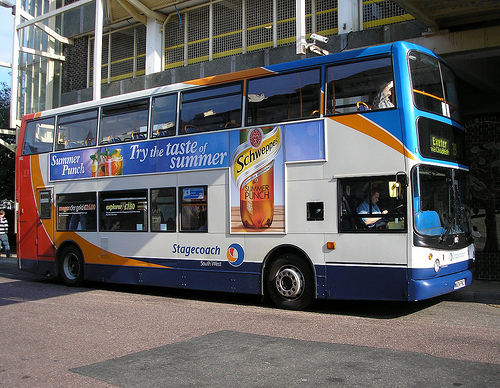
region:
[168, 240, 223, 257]
word "stagecoach" on a bus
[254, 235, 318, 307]
front right tire of a bus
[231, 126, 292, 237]
picture of a bottle on a bus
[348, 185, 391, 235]
bus driver behind the wheel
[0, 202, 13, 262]
pedestrian in a striped shirt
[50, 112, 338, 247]
advertisement for a beverage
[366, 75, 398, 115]
person in the front on the top level of the bus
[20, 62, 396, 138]
row of windows on the bus's top level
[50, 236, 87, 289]
rear tire of the bus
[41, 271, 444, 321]
shadow cast by the bus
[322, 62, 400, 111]
window on side of bus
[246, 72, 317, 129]
window on side of bus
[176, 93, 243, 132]
window on side of bus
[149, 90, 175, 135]
window on side of bus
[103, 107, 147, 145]
window on side of bus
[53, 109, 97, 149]
window on side of bus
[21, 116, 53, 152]
window on side of bus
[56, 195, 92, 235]
window on side of bus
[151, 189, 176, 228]
window on side of bus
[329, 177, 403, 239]
window on side of bus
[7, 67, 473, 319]
Double decker passenger bus.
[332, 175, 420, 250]
Bus driver sits front.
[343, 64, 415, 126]
Passenger upper deck front seat.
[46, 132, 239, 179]
Advertising along bus side.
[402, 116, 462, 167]
Exeter lettering bus destination.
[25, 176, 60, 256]
Rear door board/exit vehicle.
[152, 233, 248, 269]
Bus line Stagecoach South West.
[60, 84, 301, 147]
Most upper tier empty.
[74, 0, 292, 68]
Building wired mesh walkway.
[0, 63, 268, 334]
Shadow across bus daylight.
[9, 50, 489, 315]
Double decker bus parked on the side of the road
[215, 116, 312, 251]
Schweppes Summer Punch advertisement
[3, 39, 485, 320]
The bus is primarily white and blue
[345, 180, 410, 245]
The bus driver is in his seat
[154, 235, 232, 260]
Stagecoach written in blue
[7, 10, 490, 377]
Photo taken during the day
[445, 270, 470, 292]
The license plate is white.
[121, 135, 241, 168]
Try the taste of summer.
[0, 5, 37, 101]
The sky is clear and blue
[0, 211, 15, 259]
Person with a striped shirt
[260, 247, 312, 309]
Black front wheel on bus.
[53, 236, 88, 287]
Black back wheel of bus.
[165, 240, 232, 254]
The word 'stagecoach' written on side of bus.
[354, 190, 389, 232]
Busdriver in blue shirt sitting in bus.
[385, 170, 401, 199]
White driver's side rear view mirror.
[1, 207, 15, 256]
Person with striped top and jeans walking.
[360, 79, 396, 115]
Person sitting on top tier in first row.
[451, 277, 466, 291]
White license plate with dark lettering on front of bus.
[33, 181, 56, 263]
Orange and red door towards back of bus.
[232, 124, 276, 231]
Bottled drink featured in ad on side of bus.